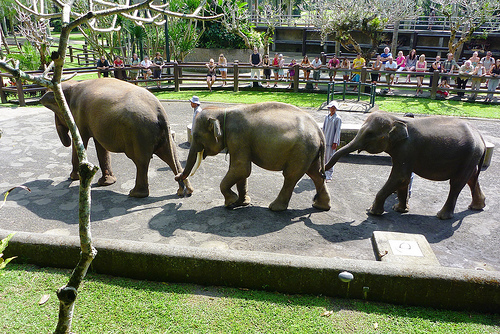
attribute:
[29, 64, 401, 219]
elephant — walking, three, medium, largest, trainer, trio, holding, large, docile, trunk, tusk, shadow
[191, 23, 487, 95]
people — watching, group, many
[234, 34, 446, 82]
visitor — watching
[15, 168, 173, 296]
tree — trunk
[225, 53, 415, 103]
fence — wooden, leaning, wood, circular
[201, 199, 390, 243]
platform — cement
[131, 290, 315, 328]
area — grassy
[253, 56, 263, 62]
top — black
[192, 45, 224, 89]
person — watching, sitting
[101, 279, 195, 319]
grass — green